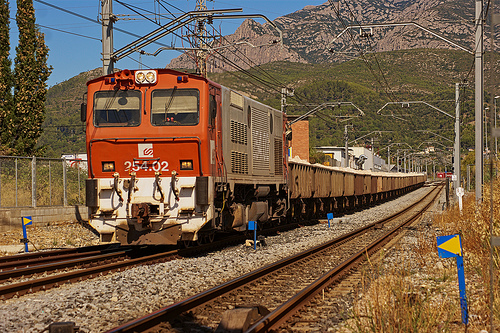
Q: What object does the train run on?
A: Tracks.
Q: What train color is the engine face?
A: Orange.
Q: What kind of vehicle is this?
A: Train.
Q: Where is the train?
A: Train tracks.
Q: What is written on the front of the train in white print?
A: White numbers.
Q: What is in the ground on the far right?
A: Blue and yellow flag.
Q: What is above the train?
A: Power lines.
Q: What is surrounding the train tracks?
A: Gravel.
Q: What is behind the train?
A: Long flatbed.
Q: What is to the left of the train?
A: Fence and trees.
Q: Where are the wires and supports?
A: Overhead.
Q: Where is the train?
A: On the tracks.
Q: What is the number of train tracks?
A: Two.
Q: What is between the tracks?
A: Gravel.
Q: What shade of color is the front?
A: Burnt orange.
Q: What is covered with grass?
A: The hillside.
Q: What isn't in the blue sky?
A: Clouds.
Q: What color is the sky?
A: Blue.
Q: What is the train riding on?
A: Tracks.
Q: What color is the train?
A: Orange.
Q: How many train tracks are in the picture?
A: Two.